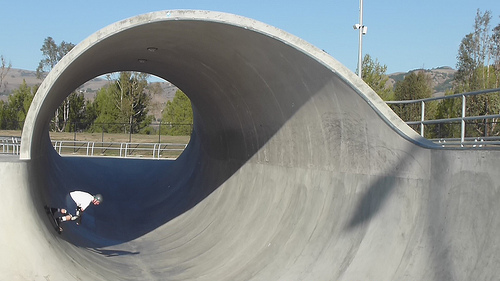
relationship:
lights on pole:
[351, 22, 372, 35] [355, 0, 367, 81]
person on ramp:
[33, 133, 134, 242] [39, 56, 346, 278]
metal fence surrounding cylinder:
[386, 86, 498, 146] [77, 52, 352, 279]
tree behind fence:
[454, 15, 485, 144] [379, 83, 484, 147]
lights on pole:
[351, 22, 372, 35] [359, 2, 363, 78]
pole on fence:
[421, 86, 463, 108] [378, 85, 495, 147]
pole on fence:
[414, 94, 431, 144] [381, 85, 496, 131]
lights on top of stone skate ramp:
[132, 43, 167, 70] [152, 22, 497, 279]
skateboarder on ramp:
[51, 177, 118, 234] [0, 11, 499, 277]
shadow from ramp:
[93, 246, 143, 262] [0, 11, 499, 277]